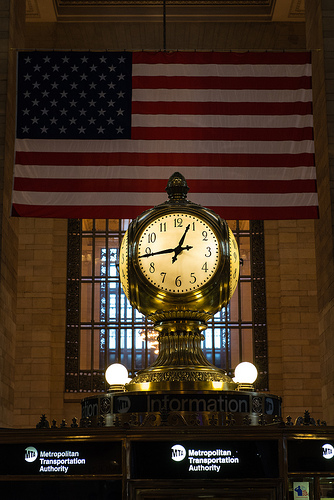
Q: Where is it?
A: This is at the station.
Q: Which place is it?
A: It is a station.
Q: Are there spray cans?
A: No, there are no spray cans.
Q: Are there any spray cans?
A: No, there are no spray cans.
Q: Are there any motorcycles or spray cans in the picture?
A: No, there are no spray cans or motorcycles.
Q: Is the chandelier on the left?
A: Yes, the chandelier is on the left of the image.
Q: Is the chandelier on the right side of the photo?
A: No, the chandelier is on the left of the image.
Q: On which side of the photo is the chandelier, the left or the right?
A: The chandelier is on the left of the image.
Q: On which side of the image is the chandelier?
A: The chandelier is on the left of the image.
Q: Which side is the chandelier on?
A: The chandelier is on the left of the image.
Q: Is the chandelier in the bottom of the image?
A: Yes, the chandelier is in the bottom of the image.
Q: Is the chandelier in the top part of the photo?
A: No, the chandelier is in the bottom of the image.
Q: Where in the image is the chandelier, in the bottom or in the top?
A: The chandelier is in the bottom of the image.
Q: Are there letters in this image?
A: Yes, there are letters.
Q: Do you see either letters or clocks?
A: Yes, there are letters.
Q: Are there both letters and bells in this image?
A: No, there are letters but no bells.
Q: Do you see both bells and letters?
A: No, there are letters but no bells.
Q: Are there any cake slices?
A: No, there are no cake slices.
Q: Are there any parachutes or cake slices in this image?
A: No, there are no cake slices or parachutes.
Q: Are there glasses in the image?
A: No, there are no glasses.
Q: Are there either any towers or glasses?
A: No, there are no glasses or towers.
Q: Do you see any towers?
A: No, there are no towers.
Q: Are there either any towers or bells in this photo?
A: No, there are no towers or bells.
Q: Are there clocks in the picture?
A: Yes, there is a clock.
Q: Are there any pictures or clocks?
A: Yes, there is a clock.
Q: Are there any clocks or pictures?
A: Yes, there is a clock.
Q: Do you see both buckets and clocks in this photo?
A: No, there is a clock but no buckets.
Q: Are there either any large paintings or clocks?
A: Yes, there is a large clock.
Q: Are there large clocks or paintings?
A: Yes, there is a large clock.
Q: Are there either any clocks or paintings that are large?
A: Yes, the clock is large.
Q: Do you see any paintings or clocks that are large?
A: Yes, the clock is large.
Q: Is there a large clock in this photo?
A: Yes, there is a large clock.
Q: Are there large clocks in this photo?
A: Yes, there is a large clock.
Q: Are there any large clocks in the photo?
A: Yes, there is a large clock.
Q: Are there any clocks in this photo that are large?
A: Yes, there is a clock that is large.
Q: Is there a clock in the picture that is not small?
A: Yes, there is a large clock.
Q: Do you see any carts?
A: No, there are no carts.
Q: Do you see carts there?
A: No, there are no carts.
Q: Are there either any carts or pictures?
A: No, there are no carts or pictures.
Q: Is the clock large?
A: Yes, the clock is large.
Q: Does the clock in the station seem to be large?
A: Yes, the clock is large.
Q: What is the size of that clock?
A: The clock is large.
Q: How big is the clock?
A: The clock is large.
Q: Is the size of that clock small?
A: No, the clock is large.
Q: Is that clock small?
A: No, the clock is large.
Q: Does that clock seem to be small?
A: No, the clock is large.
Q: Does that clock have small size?
A: No, the clock is large.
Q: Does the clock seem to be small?
A: No, the clock is large.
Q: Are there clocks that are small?
A: No, there is a clock but it is large.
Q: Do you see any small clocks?
A: No, there is a clock but it is large.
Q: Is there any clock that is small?
A: No, there is a clock but it is large.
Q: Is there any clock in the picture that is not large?
A: No, there is a clock but it is large.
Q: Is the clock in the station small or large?
A: The clock is large.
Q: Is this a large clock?
A: Yes, this is a large clock.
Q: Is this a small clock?
A: No, this is a large clock.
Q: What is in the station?
A: The clock is in the station.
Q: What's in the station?
A: The clock is in the station.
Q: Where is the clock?
A: The clock is in the station.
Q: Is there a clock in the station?
A: Yes, there is a clock in the station.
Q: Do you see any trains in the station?
A: No, there is a clock in the station.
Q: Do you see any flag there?
A: Yes, there is a flag.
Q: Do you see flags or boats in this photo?
A: Yes, there is a flag.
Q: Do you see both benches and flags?
A: No, there is a flag but no benches.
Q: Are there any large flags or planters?
A: Yes, there is a large flag.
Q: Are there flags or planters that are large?
A: Yes, the flag is large.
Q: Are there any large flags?
A: Yes, there is a large flag.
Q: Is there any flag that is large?
A: Yes, there is a flag that is large.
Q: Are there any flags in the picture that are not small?
A: Yes, there is a large flag.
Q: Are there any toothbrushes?
A: No, there are no toothbrushes.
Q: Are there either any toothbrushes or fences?
A: No, there are no toothbrushes or fences.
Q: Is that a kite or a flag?
A: That is a flag.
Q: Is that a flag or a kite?
A: That is a flag.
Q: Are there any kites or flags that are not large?
A: No, there is a flag but it is large.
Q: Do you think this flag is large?
A: Yes, the flag is large.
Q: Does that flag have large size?
A: Yes, the flag is large.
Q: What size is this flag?
A: The flag is large.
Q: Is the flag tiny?
A: No, the flag is large.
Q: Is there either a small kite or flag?
A: No, there is a flag but it is large.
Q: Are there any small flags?
A: No, there is a flag but it is large.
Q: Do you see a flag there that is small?
A: No, there is a flag but it is large.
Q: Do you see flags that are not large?
A: No, there is a flag but it is large.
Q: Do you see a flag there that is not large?
A: No, there is a flag but it is large.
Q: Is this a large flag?
A: Yes, this is a large flag.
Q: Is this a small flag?
A: No, this is a large flag.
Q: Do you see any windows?
A: Yes, there is a window.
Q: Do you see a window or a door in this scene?
A: Yes, there is a window.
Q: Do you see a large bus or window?
A: Yes, there is a large window.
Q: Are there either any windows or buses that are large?
A: Yes, the window is large.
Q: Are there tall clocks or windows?
A: Yes, there is a tall window.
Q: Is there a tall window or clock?
A: Yes, there is a tall window.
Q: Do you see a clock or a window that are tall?
A: Yes, the window is tall.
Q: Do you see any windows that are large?
A: Yes, there is a large window.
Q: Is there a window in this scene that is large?
A: Yes, there is a window that is large.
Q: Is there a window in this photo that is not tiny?
A: Yes, there is a large window.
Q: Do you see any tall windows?
A: Yes, there is a tall window.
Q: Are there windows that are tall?
A: Yes, there is a window that is tall.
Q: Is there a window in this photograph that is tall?
A: Yes, there is a window that is tall.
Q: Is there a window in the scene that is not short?
A: Yes, there is a tall window.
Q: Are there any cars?
A: No, there are no cars.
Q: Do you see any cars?
A: No, there are no cars.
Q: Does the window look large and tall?
A: Yes, the window is large and tall.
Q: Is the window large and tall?
A: Yes, the window is large and tall.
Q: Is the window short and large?
A: No, the window is large but tall.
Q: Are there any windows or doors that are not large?
A: No, there is a window but it is large.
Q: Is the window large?
A: Yes, the window is large.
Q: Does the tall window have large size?
A: Yes, the window is large.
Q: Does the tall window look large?
A: Yes, the window is large.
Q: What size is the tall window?
A: The window is large.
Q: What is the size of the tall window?
A: The window is large.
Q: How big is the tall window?
A: The window is large.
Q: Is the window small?
A: No, the window is large.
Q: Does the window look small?
A: No, the window is large.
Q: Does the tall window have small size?
A: No, the window is large.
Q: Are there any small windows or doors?
A: No, there is a window but it is large.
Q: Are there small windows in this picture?
A: No, there is a window but it is large.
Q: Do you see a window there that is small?
A: No, there is a window but it is large.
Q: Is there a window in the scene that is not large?
A: No, there is a window but it is large.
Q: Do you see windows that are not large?
A: No, there is a window but it is large.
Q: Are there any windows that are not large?
A: No, there is a window but it is large.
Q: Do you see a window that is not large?
A: No, there is a window but it is large.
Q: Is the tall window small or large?
A: The window is large.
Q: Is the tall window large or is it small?
A: The window is large.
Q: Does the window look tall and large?
A: Yes, the window is tall and large.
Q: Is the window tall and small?
A: No, the window is tall but large.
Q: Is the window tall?
A: Yes, the window is tall.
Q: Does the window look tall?
A: Yes, the window is tall.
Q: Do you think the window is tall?
A: Yes, the window is tall.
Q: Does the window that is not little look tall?
A: Yes, the window is tall.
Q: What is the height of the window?
A: The window is tall.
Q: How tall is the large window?
A: The window is tall.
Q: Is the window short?
A: No, the window is tall.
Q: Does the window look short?
A: No, the window is tall.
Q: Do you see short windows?
A: No, there is a window but it is tall.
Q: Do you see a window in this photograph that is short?
A: No, there is a window but it is tall.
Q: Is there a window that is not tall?
A: No, there is a window but it is tall.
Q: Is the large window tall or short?
A: The window is tall.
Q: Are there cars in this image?
A: No, there are no cars.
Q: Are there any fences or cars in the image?
A: No, there are no cars or fences.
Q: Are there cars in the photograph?
A: No, there are no cars.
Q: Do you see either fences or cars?
A: No, there are no cars or fences.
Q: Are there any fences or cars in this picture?
A: No, there are no cars or fences.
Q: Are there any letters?
A: Yes, there are letters.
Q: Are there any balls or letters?
A: Yes, there are letters.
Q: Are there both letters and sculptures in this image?
A: No, there are letters but no sculptures.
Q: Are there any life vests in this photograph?
A: No, there are no life vests.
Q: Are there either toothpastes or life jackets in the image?
A: No, there are no life jackets or toothpastes.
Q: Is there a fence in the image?
A: No, there are no fences.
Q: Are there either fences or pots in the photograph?
A: No, there are no fences or pots.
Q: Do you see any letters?
A: Yes, there are letters.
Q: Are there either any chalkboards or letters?
A: Yes, there are letters.